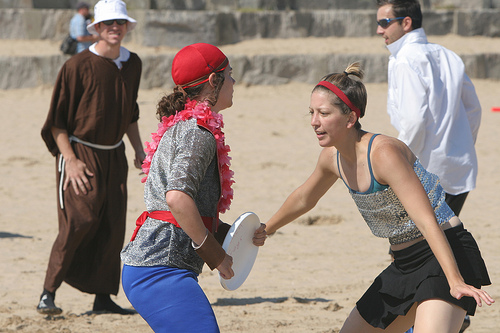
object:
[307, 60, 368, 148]
head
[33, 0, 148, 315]
guy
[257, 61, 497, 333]
girl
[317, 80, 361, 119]
headband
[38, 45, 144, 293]
dress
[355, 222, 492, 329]
black skirt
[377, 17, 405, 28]
sunglasses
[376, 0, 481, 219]
guy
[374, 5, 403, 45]
face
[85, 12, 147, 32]
sunglass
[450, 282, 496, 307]
hand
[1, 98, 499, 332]
ground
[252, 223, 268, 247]
hands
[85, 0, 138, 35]
hat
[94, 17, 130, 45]
head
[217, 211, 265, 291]
frisbee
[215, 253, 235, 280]
hand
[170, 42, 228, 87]
red cap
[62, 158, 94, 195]
hand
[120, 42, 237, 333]
girl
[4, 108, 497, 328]
beach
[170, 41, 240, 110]
head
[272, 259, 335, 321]
sand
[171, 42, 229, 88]
cap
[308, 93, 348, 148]
face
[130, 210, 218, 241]
belt